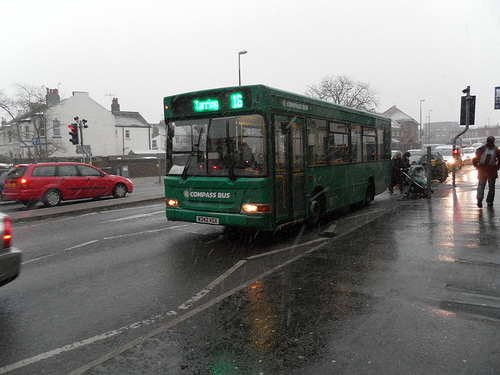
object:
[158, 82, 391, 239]
bus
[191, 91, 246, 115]
sign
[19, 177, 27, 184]
lights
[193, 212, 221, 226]
license plate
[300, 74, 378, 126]
tree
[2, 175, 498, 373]
road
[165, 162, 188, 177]
sign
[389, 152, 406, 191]
woman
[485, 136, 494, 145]
head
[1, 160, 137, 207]
station wagon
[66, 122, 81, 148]
stoplight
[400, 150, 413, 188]
person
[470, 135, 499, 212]
man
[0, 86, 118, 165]
townhouses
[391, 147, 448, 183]
bus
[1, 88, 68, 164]
tree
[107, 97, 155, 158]
building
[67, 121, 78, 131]
is red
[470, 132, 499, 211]
is walking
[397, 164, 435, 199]
stroller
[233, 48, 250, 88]
light pole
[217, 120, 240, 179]
wiper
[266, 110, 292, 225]
door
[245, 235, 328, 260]
line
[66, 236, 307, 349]
rain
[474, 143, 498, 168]
backpack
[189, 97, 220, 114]
is green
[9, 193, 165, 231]
barrier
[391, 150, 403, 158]
cap